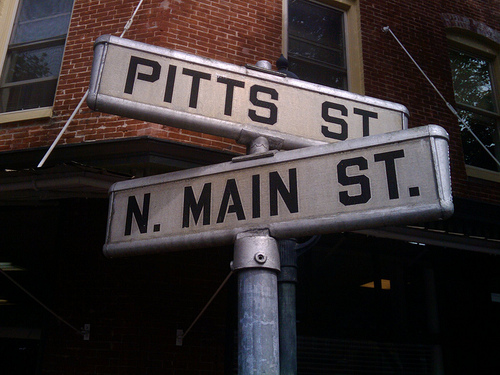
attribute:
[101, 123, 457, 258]
sign — white, rectangular, here, gray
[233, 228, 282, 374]
pole — metallic, silver, white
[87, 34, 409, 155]
sign — white, here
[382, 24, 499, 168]
wire — gray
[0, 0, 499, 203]
building — here, brick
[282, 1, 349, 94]
window — here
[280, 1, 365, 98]
frame — yellow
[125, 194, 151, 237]
letter — black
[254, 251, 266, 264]
screw — here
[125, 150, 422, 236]
writing — black, here, white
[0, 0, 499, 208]
wall — here